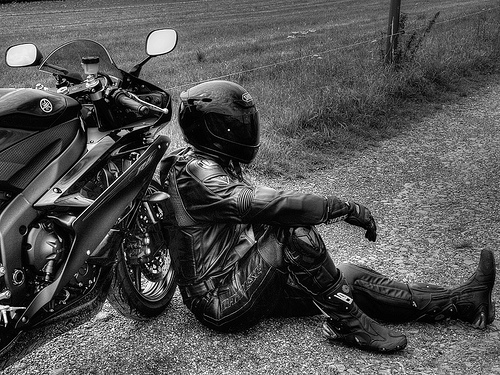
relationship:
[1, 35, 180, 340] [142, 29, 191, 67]
motorcycle has mirror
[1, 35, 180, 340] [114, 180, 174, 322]
motorcycle has tire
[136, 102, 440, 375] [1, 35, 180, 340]
man near motorcycle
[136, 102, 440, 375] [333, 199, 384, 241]
motorcyclist has glove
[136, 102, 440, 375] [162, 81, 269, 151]
motorcyclist has helmet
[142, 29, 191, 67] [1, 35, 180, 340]
mirror on motorcycle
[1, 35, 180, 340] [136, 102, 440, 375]
motorcycle behind motorcyclist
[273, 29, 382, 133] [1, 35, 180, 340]
grass behind motorcycle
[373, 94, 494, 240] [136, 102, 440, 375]
road under motorcyclist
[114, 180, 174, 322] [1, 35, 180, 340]
tire on motorcycle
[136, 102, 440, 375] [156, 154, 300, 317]
motorcyclist wears jacket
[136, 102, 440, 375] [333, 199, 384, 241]
motorcyclist wears glove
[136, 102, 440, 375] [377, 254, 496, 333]
motorcyclist wears boot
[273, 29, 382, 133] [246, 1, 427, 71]
grass near fence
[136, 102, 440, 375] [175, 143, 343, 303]
motorcyclist wears leather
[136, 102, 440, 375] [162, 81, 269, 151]
motorcyclist wears helmet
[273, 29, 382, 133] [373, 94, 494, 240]
grass behind road